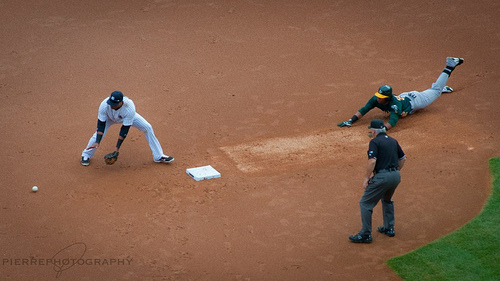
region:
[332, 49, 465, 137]
Baseball player sliding into second base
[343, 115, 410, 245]
Second base umpire with black shirt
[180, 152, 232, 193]
Second base on baseball infield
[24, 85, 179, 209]
Baseball player ready to catch baseball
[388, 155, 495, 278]
Baseball infield green grass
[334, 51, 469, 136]
Oakland Athletics player sliding into second base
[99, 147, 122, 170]
Baseball player leather glove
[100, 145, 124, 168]
Right handed leather baseball glove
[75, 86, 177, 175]
Baseball player with white uniform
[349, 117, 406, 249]
Umpire with black shirt and gray pants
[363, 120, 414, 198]
A umpire dressed in black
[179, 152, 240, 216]
white square baseball plate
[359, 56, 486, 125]
A basefall player diving in the dirt.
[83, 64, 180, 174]
A baseball player ready to catch a ball.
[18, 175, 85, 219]
A white baseball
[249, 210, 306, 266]
Foot tracks in dirt.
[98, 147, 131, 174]
A baseball mitt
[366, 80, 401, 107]
A hard green baseball helmet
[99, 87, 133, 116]
A dark blue baseball cap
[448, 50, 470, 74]
a white tennis shoe.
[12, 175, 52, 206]
Ball on the ground.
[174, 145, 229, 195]
The base is white.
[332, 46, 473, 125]
Player on the ground.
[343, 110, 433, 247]
The referee is watching the player.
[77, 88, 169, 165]
Man has a mitt.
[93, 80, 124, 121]
The man is wearing a hat.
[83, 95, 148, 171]
The uniform is white.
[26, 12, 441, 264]
The ground is brown.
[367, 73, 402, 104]
Man is wearing a helmet.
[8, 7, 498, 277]
Taken at a baseball game.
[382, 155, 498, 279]
green grass on a baseball field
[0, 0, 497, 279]
the dirt on a baseball field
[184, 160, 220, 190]
a white square base on the field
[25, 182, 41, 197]
a baseball on the ground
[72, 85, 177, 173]
baseball player catching a ball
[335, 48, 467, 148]
baseball player sliding to the base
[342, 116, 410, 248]
umpire watching the baseball players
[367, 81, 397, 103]
green batting helmet on the man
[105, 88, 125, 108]
black and white baseball on the man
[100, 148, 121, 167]
leather mitt on the baseball player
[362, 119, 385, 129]
ref's official baseball cap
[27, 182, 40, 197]
baseball rollin', they hatin'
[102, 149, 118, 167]
black and brown leather baseball mitt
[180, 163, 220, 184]
third base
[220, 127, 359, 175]
slide mark from baseball sliders before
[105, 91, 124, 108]
navy blue baseball cap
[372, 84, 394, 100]
green and yellow batting helmet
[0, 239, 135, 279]
name and logo of the photographer who took this photo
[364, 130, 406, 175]
super ref's stance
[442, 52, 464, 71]
high-top cleats